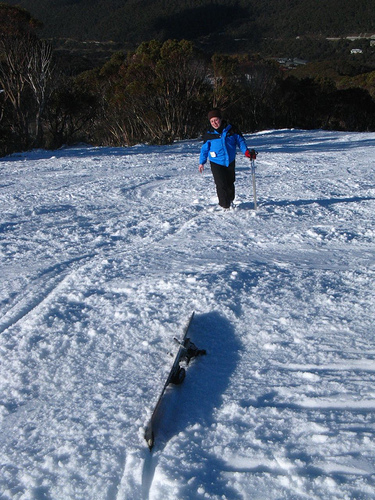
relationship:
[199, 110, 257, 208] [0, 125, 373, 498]
person walking on snow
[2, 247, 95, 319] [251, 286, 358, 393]
tracks in snow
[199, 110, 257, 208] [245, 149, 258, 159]
person wearing glove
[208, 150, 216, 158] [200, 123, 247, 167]
paper in coat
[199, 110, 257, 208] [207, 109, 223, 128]
person has head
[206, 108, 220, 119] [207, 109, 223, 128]
hat on head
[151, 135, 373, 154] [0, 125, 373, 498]
shadow on snow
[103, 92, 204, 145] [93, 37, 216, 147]
branches on tree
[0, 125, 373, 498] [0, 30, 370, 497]
snow covering ground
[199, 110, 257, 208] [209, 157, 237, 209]
person wearing pants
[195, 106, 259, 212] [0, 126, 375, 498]
person on ground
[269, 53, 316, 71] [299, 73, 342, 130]
roof among tree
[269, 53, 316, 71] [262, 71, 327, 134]
roof among tree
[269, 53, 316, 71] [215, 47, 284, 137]
roof among tree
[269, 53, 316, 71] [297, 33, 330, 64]
roof among tree